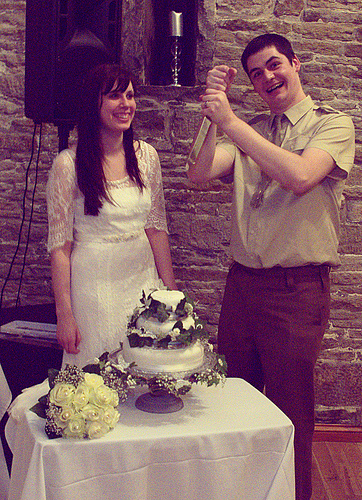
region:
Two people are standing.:
[74, 66, 361, 241]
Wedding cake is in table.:
[123, 288, 204, 391]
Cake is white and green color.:
[131, 299, 208, 399]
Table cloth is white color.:
[9, 405, 302, 477]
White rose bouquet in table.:
[41, 374, 129, 456]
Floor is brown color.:
[317, 452, 353, 490]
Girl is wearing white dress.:
[60, 171, 155, 282]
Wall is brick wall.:
[294, 9, 343, 78]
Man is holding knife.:
[179, 57, 264, 176]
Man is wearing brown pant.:
[220, 237, 322, 385]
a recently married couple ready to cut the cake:
[27, 28, 354, 408]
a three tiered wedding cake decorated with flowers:
[111, 286, 227, 411]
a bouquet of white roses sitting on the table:
[42, 365, 122, 444]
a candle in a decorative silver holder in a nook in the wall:
[164, 8, 197, 90]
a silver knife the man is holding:
[189, 61, 222, 169]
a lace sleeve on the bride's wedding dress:
[43, 150, 76, 254]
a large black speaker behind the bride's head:
[19, 2, 111, 123]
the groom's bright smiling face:
[242, 56, 298, 102]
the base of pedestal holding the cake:
[135, 393, 195, 416]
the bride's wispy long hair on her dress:
[73, 134, 119, 215]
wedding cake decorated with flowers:
[104, 284, 224, 393]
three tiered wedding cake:
[116, 286, 218, 379]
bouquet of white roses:
[35, 365, 122, 433]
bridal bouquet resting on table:
[30, 369, 125, 438]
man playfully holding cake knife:
[201, 31, 354, 266]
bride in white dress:
[47, 63, 175, 299]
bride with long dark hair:
[53, 59, 175, 267]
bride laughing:
[44, 61, 173, 261]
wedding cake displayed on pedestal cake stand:
[106, 285, 224, 417]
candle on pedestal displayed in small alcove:
[136, 0, 223, 94]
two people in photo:
[73, 37, 348, 381]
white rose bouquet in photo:
[35, 360, 142, 462]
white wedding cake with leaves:
[117, 287, 234, 403]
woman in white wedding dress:
[37, 99, 194, 371]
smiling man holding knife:
[183, 51, 358, 268]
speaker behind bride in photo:
[12, 8, 160, 178]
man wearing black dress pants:
[210, 250, 346, 497]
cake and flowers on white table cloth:
[14, 283, 320, 494]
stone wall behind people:
[8, 99, 333, 317]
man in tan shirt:
[196, 91, 359, 301]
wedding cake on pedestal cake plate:
[104, 348, 216, 414]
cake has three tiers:
[120, 289, 204, 368]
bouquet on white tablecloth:
[4, 376, 295, 498]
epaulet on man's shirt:
[313, 104, 337, 115]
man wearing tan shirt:
[216, 93, 357, 266]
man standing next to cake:
[185, 32, 353, 496]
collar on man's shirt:
[260, 93, 310, 128]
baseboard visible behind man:
[313, 425, 361, 442]